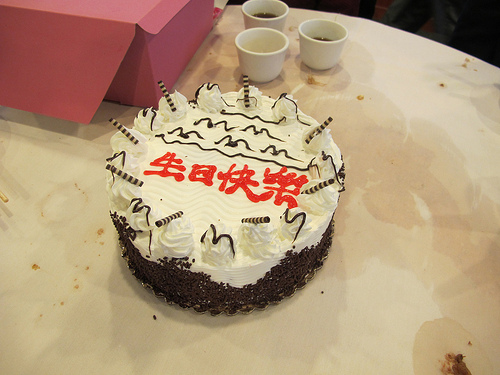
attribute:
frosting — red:
[141, 150, 309, 211]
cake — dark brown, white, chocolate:
[101, 76, 347, 317]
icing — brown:
[168, 112, 302, 167]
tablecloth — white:
[0, 3, 500, 373]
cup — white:
[297, 11, 356, 71]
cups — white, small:
[229, 4, 353, 83]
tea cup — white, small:
[299, 17, 344, 67]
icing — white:
[107, 74, 345, 286]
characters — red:
[146, 146, 325, 211]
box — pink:
[46, 20, 141, 110]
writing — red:
[144, 151, 307, 211]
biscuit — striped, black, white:
[238, 68, 253, 113]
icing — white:
[107, 87, 329, 278]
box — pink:
[2, 2, 213, 120]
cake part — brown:
[115, 214, 337, 316]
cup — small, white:
[211, 21, 306, 85]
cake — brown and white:
[80, 74, 410, 366]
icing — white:
[191, 165, 293, 235]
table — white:
[3, 0, 498, 373]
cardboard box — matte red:
[5, 2, 215, 124]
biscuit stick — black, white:
[236, 213, 268, 229]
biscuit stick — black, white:
[154, 210, 189, 230]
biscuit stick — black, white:
[97, 165, 146, 189]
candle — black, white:
[301, 177, 336, 195]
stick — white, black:
[151, 202, 193, 230]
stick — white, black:
[104, 157, 145, 184]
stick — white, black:
[111, 115, 141, 149]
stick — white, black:
[155, 78, 181, 114]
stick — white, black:
[239, 65, 255, 105]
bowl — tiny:
[238, 34, 286, 79]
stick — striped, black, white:
[101, 161, 150, 196]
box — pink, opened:
[0, 0, 231, 130]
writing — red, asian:
[155, 153, 299, 198]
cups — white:
[230, 54, 298, 85]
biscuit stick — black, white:
[304, 113, 333, 154]